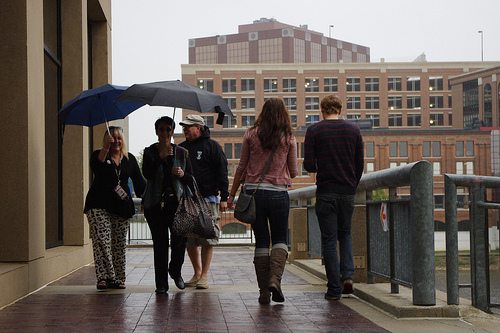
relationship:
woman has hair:
[230, 97, 297, 307] [252, 101, 293, 151]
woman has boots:
[230, 97, 297, 307] [253, 244, 289, 304]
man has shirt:
[180, 117, 226, 290] [203, 192, 220, 205]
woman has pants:
[88, 126, 146, 289] [88, 207, 126, 283]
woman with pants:
[88, 126, 146, 289] [88, 207, 126, 283]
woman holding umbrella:
[88, 126, 146, 289] [59, 86, 147, 126]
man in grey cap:
[180, 117, 226, 290] [184, 116, 209, 129]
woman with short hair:
[145, 117, 195, 295] [155, 118, 176, 136]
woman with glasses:
[145, 117, 195, 295] [158, 125, 175, 135]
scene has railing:
[2, 0, 498, 333] [358, 165, 499, 303]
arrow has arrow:
[379, 206, 387, 227] [379, 209, 387, 224]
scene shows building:
[2, 0, 498, 333] [183, 62, 499, 227]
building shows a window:
[183, 62, 499, 227] [387, 80, 405, 93]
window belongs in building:
[389, 140, 398, 158] [175, 130, 499, 231]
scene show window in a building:
[2, 0, 498, 333] [183, 62, 499, 227]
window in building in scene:
[387, 80, 405, 93] [2, 0, 498, 333]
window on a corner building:
[485, 84, 491, 99] [449, 69, 500, 128]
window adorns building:
[387, 80, 405, 93] [183, 62, 499, 227]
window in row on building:
[387, 80, 405, 93] [183, 62, 499, 227]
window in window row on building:
[387, 80, 405, 93] [183, 62, 499, 227]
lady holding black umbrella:
[145, 117, 195, 295] [126, 80, 234, 116]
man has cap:
[180, 117, 226, 290] [184, 116, 209, 129]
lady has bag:
[145, 117, 195, 295] [175, 178, 220, 240]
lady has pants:
[88, 126, 146, 289] [88, 207, 126, 283]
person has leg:
[306, 96, 359, 298] [319, 198, 343, 296]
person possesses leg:
[88, 126, 146, 289] [84, 209, 118, 284]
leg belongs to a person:
[147, 207, 169, 293] [145, 117, 195, 295]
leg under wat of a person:
[147, 207, 169, 293] [145, 117, 195, 295]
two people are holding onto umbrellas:
[89, 117, 185, 295] [62, 83, 234, 126]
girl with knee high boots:
[230, 97, 297, 307] [253, 244, 289, 304]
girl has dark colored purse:
[145, 117, 195, 295] [175, 178, 220, 240]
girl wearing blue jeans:
[230, 97, 297, 307] [248, 189, 292, 248]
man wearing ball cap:
[180, 117, 226, 290] [184, 116, 209, 129]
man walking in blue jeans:
[306, 96, 359, 298] [317, 194, 354, 299]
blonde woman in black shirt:
[88, 126, 146, 289] [84, 150, 145, 217]